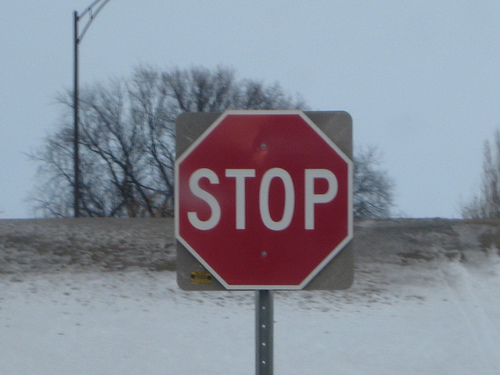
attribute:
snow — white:
[1, 270, 496, 375]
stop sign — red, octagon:
[176, 110, 351, 289]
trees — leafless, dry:
[27, 66, 398, 220]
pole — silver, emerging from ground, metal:
[254, 287, 275, 374]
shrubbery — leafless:
[458, 126, 499, 249]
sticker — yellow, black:
[189, 272, 216, 283]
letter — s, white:
[186, 167, 220, 231]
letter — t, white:
[224, 168, 256, 232]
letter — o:
[259, 167, 295, 232]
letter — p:
[303, 168, 338, 231]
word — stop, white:
[187, 166, 338, 229]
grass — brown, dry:
[1, 220, 175, 276]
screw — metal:
[259, 142, 268, 149]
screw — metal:
[261, 251, 268, 258]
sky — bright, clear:
[4, 2, 498, 217]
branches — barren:
[71, 81, 127, 139]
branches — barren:
[131, 68, 163, 118]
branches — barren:
[161, 68, 192, 111]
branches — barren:
[190, 65, 214, 104]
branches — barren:
[211, 63, 234, 107]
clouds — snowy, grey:
[3, 0, 496, 121]